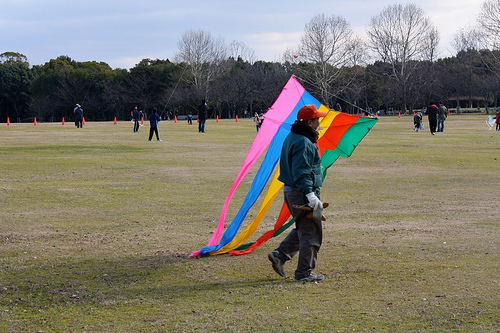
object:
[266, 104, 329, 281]
man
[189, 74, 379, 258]
kite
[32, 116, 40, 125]
cones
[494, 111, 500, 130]
person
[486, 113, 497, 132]
kite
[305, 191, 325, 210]
gloves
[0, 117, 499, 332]
field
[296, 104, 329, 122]
cap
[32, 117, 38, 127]
cone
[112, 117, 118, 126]
cone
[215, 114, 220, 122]
cone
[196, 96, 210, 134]
guy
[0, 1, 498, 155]
background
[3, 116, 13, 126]
cone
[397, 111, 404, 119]
cone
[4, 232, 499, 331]
ground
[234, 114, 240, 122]
cone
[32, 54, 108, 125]
trees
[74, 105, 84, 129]
people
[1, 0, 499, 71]
sky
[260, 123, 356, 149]
colors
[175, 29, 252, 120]
tree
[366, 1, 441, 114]
tree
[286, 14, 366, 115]
tree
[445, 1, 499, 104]
tree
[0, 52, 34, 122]
tree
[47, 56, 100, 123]
tree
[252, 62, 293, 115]
tree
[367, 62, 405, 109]
tree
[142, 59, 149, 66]
leaves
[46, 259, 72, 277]
grass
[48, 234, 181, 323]
patches